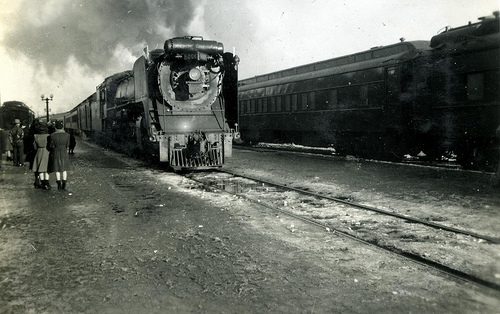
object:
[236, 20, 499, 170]
train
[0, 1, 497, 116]
sky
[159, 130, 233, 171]
headlight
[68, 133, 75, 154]
people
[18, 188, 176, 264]
ground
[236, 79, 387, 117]
windows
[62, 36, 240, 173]
train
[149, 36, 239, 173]
front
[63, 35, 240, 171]
engine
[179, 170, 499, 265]
puddle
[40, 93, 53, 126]
pole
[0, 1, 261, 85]
steam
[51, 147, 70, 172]
skirt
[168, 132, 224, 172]
safety ram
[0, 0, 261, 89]
smoke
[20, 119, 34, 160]
persons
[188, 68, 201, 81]
light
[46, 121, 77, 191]
dresss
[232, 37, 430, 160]
cars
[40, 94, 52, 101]
lights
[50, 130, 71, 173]
jackets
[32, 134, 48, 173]
jackets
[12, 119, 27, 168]
man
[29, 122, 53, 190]
couple